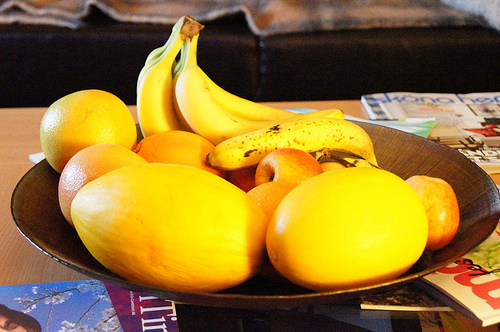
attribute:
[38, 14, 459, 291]
fruit — delicious, delightful, tasty, flavorful, nice, great, arranged, various, yellow, large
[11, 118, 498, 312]
bowl — nice, brown, round, large, big, wooden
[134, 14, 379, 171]
bananas — yellow, ripe, small, bunched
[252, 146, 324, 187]
apple — red, yellow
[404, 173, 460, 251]
apple — red, yellow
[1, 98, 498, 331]
table — light brown, wood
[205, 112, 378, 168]
banana — spotted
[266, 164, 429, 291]
mango — yellow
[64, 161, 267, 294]
mango — yellow